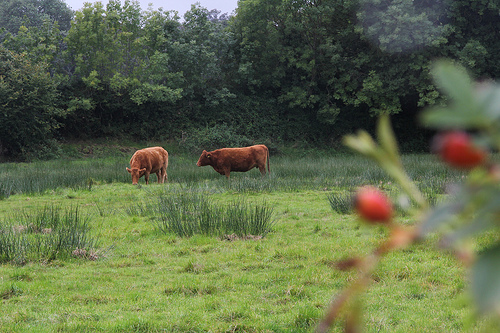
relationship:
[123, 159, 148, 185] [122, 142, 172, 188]
head of cow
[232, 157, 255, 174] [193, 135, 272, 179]
stomach of cow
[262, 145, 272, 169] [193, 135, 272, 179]
tail of cow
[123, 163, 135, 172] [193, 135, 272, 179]
ear of cow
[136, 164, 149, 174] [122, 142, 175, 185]
ear of cow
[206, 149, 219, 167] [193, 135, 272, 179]
neck of cow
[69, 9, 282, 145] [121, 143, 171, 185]
trees behind cow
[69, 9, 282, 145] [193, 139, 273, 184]
trees behind cow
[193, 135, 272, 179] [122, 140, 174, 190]
cow looking at cow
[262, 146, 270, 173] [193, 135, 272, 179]
tail of cow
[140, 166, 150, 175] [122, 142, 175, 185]
ear of cow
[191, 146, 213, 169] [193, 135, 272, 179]
head of cow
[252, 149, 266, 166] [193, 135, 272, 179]
hip of cow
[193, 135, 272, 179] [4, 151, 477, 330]
cow in field